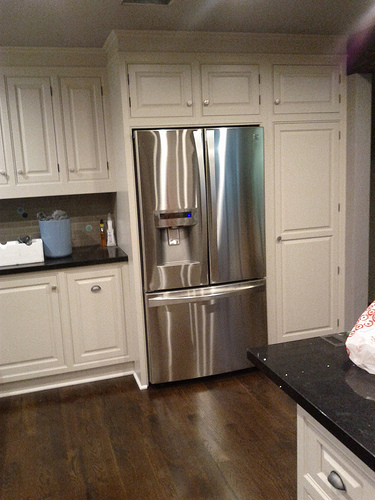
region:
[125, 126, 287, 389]
large stainless steel refrigerator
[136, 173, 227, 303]
ice dispenser on refrigerator door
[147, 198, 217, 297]
blue light on ice dispenser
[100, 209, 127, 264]
white container on counter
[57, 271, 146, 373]
white cupboard with silver handle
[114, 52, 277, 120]
white cupboards with white handles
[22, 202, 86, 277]
blue container on countertop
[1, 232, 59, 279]
white object on countertop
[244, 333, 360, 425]
black countertop with white specks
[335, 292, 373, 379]
white and red bag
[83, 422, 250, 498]
The floors are made of wood.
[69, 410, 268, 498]
The floors are brown.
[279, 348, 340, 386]
The countertop is black.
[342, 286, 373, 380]
A plastic bag.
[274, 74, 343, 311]
The cabinets are white.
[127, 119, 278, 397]
The refrigerator is stainless steel.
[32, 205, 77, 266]
A blue bucket.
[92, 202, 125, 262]
A couple of bottles.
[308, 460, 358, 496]
The drawer handles are gray.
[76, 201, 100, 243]
The wall is tile.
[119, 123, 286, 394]
stainless steel refrigerator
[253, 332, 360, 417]
gray granite counter top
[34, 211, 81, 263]
light blue container on the counter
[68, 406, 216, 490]
dark brown wood floor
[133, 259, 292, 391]
freezer on the bottom of the refrigerator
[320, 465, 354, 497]
stainless steel drawer pulls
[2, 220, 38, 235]
brown tile back splash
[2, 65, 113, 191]
white lacquered cabinets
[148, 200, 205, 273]
digital ice and water dispensor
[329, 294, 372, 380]
a plastic target bag on the island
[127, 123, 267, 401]
a large silve refrigerator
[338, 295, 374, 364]
a white plastic Target bag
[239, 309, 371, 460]
a black countertop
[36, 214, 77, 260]
a blue bucket on a sink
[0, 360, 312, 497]
a dark brown hardwood floor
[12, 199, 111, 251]
a white tile backsplash behind a counter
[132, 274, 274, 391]
a pull out freezer drawer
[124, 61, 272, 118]
white cupboards above the refrigerator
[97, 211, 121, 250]
two bottles of cleaner on the counter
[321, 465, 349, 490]
a metal drawer pull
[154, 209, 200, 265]
ice cube dispenser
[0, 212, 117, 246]
brick design back splash wall covering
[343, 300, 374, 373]
plastic shopping bag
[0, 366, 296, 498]
laminated wood design flooring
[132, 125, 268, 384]
stainless steel refrigerater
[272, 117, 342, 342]
tall pantry cabinet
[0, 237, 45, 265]
Styrofoam container sitting on counter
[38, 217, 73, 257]
rounded blue plastic container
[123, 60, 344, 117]
three white overhead cabinets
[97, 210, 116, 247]
two squirt bottle containers of liquid